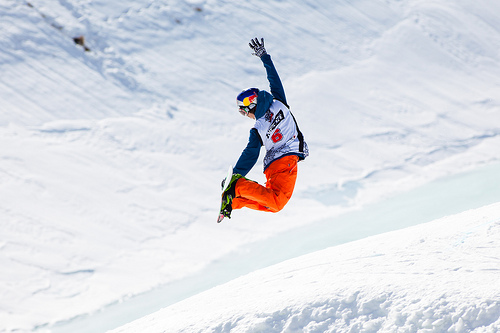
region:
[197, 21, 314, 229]
snow boarder doing trick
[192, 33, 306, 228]
snow boarder in air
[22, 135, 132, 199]
white snow on hill side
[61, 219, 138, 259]
white snow on hill side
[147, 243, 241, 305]
white snow on hill side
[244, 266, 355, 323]
white snow on hill side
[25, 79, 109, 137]
white snow on hill side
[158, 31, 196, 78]
white snow on hill side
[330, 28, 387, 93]
white snow on hill side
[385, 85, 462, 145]
white snow on hill side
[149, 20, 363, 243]
man snow boarding in air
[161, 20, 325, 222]
man grabbing snow board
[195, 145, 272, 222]
hand grabbing snow board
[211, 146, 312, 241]
orange snow board pants on man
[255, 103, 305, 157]
white snow board top on person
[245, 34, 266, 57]
white and black snow gloves on hand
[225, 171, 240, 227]
green snow shoes on board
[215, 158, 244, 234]
long white snow board on feet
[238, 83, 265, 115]
red bull logo on helmet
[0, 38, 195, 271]
snow covering mountain side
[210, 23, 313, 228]
snowboarder performing a trick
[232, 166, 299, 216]
orange pants of the snowboarder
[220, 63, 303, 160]
blue coat of the snowboarder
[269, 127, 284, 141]
red number on white background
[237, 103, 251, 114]
goggles of the snowboarder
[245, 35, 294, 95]
snowboarder's extended arm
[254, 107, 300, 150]
white race bib of snowboarder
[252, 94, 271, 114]
hood of blue coat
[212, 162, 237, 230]
snowboard of the snowboarder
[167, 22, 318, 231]
snowboarder in the air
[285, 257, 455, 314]
a place full of snow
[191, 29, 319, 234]
a person is jumping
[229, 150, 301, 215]
a person wearing orange color pant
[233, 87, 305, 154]
a person wearing blue color jacket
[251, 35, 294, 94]
a person lifting his hand up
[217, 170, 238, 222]
a person wearing green color shoes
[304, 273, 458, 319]
lot of snows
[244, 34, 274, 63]
blue color gloves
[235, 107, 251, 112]
a person wearing eyeglass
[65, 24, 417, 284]
a person jumping in the snow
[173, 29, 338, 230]
a snowboarder in the air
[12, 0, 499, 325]
snow fully covers the ground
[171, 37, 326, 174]
a blue and white top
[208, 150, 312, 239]
orange pants on legs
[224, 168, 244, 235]
green and black boots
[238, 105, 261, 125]
goggles worn on face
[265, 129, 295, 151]
number 6 on back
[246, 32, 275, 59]
black and white glove on hand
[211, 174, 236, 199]
one hand holding on to snowboard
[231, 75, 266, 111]
a blue helmet on head